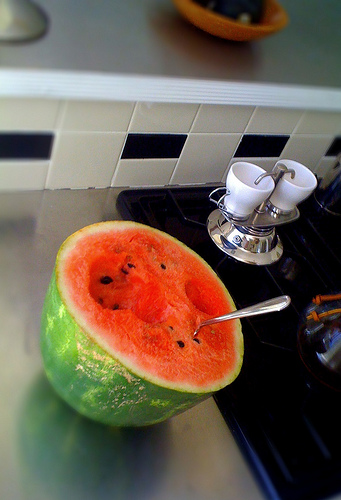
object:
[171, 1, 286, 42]
bowl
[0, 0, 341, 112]
counter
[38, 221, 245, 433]
watermelon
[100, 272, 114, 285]
seeds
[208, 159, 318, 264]
espressor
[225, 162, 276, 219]
cup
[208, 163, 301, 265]
machine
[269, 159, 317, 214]
cup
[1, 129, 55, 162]
tile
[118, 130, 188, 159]
tile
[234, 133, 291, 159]
tile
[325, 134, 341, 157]
tile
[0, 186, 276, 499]
counter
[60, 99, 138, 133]
tiles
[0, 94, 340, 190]
backsplash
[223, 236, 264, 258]
reflection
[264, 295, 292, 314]
part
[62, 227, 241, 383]
red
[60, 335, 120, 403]
rind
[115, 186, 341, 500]
tray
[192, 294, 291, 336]
fork